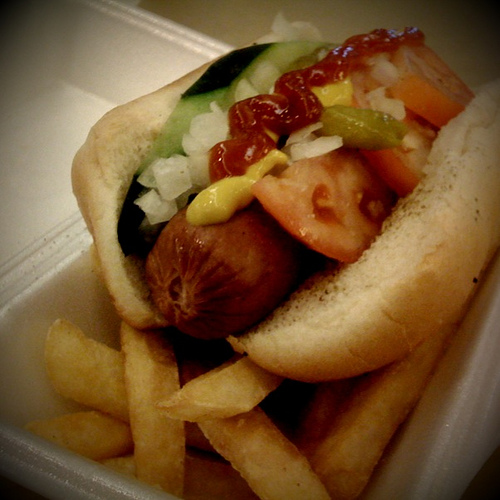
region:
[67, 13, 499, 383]
hot dog loaded with toppings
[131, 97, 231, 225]
minced onions on a hot dog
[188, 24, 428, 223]
a line of ketchup and mustard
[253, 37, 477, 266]
a few tomatoes on a hot dog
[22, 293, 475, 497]
a bunch of french fries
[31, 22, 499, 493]
a hot dog and fries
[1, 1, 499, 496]
food in a styrofoam box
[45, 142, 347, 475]
fries under the hotdog sandwich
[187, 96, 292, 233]
mustard and ketchup on the hotdog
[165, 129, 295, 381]
mustard and ketchup on the hotdog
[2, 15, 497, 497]
this is a hot dog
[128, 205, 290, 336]
this is a sausage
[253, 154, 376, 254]
this is a tomato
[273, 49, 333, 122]
this is tomato sauce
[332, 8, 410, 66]
this is tomato sauce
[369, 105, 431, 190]
this is a slice of tomato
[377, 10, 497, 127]
this is a slice of tomato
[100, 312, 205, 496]
this is a piece of fried potato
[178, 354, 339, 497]
this is a piece of fried potato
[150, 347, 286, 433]
cooked french fry made of a potato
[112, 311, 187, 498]
cooked french fry made of a potato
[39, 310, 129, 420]
cooked french fry made of a potato